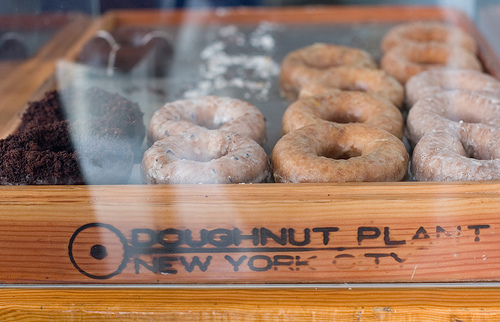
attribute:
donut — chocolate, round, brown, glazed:
[15, 83, 146, 158]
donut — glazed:
[270, 122, 410, 182]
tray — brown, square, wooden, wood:
[2, 9, 498, 283]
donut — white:
[408, 121, 498, 182]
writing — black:
[68, 222, 488, 280]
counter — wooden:
[2, 286, 498, 320]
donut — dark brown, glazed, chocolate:
[0, 110, 133, 185]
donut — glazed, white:
[405, 90, 499, 147]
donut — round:
[298, 64, 405, 106]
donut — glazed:
[146, 94, 268, 151]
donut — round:
[379, 41, 482, 84]